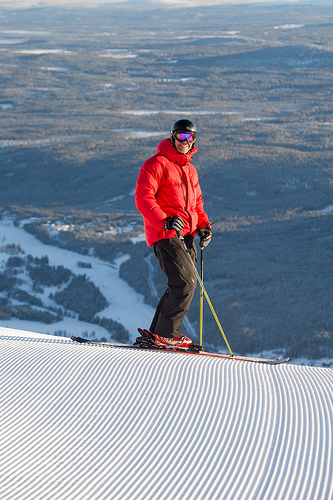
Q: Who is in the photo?
A: A skier.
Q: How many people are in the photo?
A: 1.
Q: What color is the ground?
A: White.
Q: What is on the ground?
A: Snow.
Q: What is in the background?
A: Trees.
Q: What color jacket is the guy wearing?
A: Red.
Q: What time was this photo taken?
A: Daytime.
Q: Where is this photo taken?
A: At the top of the mountain.